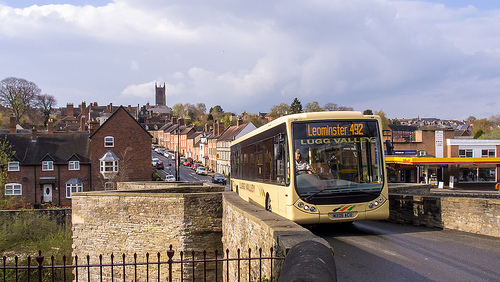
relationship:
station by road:
[389, 155, 497, 190] [152, 147, 497, 281]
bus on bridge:
[228, 111, 393, 232] [68, 179, 314, 278]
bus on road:
[228, 111, 393, 232] [152, 147, 497, 281]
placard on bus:
[304, 120, 366, 140] [228, 111, 393, 232]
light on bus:
[299, 200, 316, 210] [228, 111, 393, 232]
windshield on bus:
[295, 133, 382, 197] [228, 111, 393, 232]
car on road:
[196, 167, 211, 178] [152, 147, 497, 281]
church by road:
[144, 81, 177, 125] [152, 147, 497, 281]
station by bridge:
[389, 155, 497, 190] [68, 179, 314, 278]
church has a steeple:
[144, 81, 177, 125] [152, 81, 168, 107]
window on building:
[68, 159, 79, 170] [0, 103, 153, 211]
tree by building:
[1, 76, 42, 124] [0, 103, 153, 211]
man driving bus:
[290, 147, 314, 176] [228, 111, 393, 232]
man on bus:
[290, 147, 314, 176] [228, 111, 393, 232]